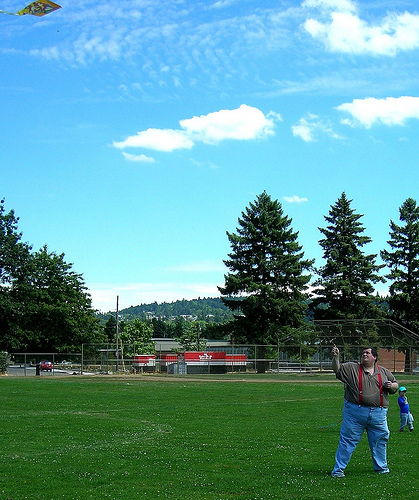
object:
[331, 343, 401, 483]
boy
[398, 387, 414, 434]
boy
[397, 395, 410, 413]
shirt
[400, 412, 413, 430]
pants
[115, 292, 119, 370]
telephone pole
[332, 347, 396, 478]
guy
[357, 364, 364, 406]
suspenders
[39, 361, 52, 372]
car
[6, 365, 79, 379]
parking lot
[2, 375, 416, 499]
field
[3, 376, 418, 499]
grass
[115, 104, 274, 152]
clouds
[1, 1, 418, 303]
sky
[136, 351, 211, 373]
buildings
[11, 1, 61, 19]
kite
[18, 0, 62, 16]
pattern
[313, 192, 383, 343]
trees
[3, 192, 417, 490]
park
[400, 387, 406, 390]
hat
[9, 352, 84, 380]
street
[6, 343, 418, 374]
fence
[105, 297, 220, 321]
mountain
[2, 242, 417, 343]
background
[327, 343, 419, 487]
man and child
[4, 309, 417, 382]
distance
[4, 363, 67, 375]
road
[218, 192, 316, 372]
tree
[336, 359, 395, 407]
shirt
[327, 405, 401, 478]
jeans